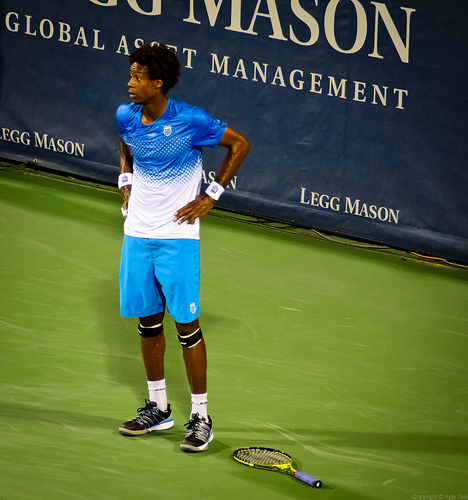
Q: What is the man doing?
A: Standing.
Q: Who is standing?
A: The man.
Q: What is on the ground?
A: A racket.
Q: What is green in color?
A: The court.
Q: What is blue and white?
A: Man's outfit.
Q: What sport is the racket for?
A: Tennis.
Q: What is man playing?
A: Tennis.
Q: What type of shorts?
A: Tennis.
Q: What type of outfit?
A: Tennis.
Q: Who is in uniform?
A: Tennis player.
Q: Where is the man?
A: On ground.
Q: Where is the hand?
A: On waist.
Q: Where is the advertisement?
A: Behind player.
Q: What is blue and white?
A: T-shirt.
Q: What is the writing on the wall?
A: Advertisement.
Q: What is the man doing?
A: Standing.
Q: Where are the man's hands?
A: On his waist.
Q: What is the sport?
A: Tennis.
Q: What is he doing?
A: Standing.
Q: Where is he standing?
A: Tennis court.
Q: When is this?
A: During the day.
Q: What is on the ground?
A: Tennis racket.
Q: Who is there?
A: Man.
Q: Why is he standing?
A: Standing.